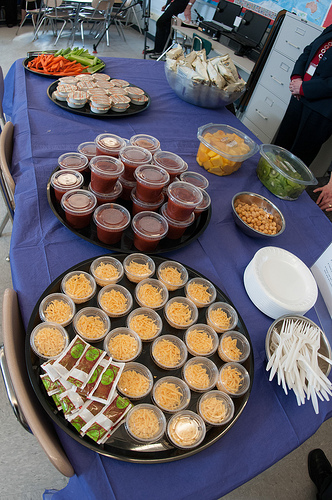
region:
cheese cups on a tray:
[27, 252, 251, 452]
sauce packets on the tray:
[38, 332, 131, 446]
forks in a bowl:
[260, 310, 330, 412]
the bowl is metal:
[259, 309, 328, 383]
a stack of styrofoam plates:
[238, 248, 319, 315]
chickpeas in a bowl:
[228, 186, 291, 241]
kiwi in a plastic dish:
[254, 140, 317, 203]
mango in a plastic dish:
[196, 111, 252, 173]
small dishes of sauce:
[37, 132, 216, 255]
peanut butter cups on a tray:
[52, 72, 147, 114]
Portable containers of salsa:
[49, 131, 200, 252]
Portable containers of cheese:
[129, 250, 245, 448]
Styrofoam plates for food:
[249, 242, 316, 313]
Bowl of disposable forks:
[264, 312, 329, 410]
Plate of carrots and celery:
[23, 46, 99, 71]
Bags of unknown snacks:
[163, 43, 243, 105]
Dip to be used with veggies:
[52, 72, 145, 111]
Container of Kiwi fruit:
[259, 141, 307, 197]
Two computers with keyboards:
[204, 0, 260, 43]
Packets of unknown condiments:
[54, 358, 118, 426]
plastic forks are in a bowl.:
[267, 325, 325, 404]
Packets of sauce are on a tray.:
[57, 354, 115, 445]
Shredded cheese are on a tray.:
[61, 283, 224, 329]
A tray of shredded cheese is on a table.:
[69, 265, 241, 328]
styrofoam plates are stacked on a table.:
[249, 244, 321, 307]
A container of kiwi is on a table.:
[256, 148, 307, 202]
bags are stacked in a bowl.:
[167, 42, 227, 112]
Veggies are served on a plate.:
[29, 54, 126, 75]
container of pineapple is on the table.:
[203, 110, 243, 188]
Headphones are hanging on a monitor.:
[211, 2, 262, 29]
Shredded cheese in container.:
[129, 411, 168, 445]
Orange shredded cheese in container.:
[174, 411, 195, 437]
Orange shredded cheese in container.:
[201, 393, 229, 416]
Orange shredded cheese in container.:
[156, 381, 181, 397]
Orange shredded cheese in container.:
[123, 371, 147, 394]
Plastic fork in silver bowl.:
[266, 321, 308, 370]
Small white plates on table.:
[247, 276, 313, 318]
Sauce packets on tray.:
[67, 358, 114, 418]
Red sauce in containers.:
[66, 144, 168, 209]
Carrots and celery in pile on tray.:
[35, 41, 97, 71]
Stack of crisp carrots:
[36, 55, 61, 68]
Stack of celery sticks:
[65, 48, 86, 61]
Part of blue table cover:
[209, 453, 249, 471]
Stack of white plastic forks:
[276, 329, 310, 366]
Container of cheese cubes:
[192, 119, 257, 175]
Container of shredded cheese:
[150, 335, 186, 365]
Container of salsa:
[129, 207, 169, 252]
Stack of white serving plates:
[242, 243, 318, 319]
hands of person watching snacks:
[285, 75, 305, 97]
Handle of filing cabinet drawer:
[250, 107, 268, 125]